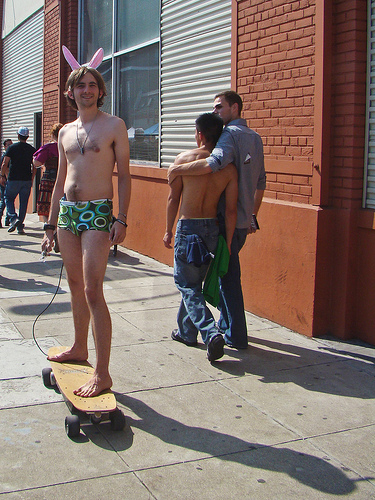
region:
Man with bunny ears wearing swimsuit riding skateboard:
[38, 61, 133, 393]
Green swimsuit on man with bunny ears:
[51, 195, 113, 232]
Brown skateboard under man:
[39, 340, 123, 433]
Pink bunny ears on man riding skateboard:
[60, 45, 102, 68]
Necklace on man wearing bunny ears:
[71, 114, 90, 159]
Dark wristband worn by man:
[36, 218, 56, 230]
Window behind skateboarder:
[76, 0, 160, 162]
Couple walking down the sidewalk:
[161, 85, 266, 358]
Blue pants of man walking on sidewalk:
[168, 214, 219, 336]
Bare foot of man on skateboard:
[74, 376, 118, 398]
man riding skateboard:
[39, 45, 130, 398]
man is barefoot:
[42, 64, 133, 396]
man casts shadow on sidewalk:
[111, 386, 356, 494]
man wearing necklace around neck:
[72, 108, 102, 153]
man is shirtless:
[40, 42, 126, 394]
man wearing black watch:
[41, 222, 53, 229]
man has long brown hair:
[63, 65, 104, 106]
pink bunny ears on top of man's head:
[58, 42, 103, 67]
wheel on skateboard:
[64, 413, 79, 435]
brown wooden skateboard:
[47, 343, 116, 412]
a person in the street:
[32, 54, 135, 401]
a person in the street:
[156, 103, 241, 370]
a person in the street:
[32, 120, 80, 251]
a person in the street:
[2, 125, 36, 234]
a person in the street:
[1, 137, 18, 215]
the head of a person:
[62, 64, 111, 113]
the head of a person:
[187, 106, 223, 148]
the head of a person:
[208, 88, 241, 120]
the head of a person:
[15, 122, 31, 142]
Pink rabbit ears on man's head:
[53, 42, 106, 65]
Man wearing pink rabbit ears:
[49, 45, 132, 396]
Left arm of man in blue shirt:
[165, 114, 233, 174]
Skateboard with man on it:
[26, 341, 125, 436]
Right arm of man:
[219, 156, 239, 265]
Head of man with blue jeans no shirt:
[189, 111, 221, 147]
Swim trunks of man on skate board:
[50, 192, 115, 234]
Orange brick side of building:
[225, 5, 315, 203]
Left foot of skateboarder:
[71, 362, 123, 398]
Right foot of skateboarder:
[43, 337, 89, 367]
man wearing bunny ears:
[36, 31, 135, 79]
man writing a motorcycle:
[7, 331, 150, 462]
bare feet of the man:
[57, 346, 125, 417]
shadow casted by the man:
[153, 399, 351, 490]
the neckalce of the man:
[72, 126, 98, 163]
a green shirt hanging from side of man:
[217, 240, 238, 325]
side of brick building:
[239, 5, 316, 106]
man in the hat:
[19, 122, 39, 147]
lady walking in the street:
[31, 132, 55, 211]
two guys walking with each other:
[166, 96, 298, 333]